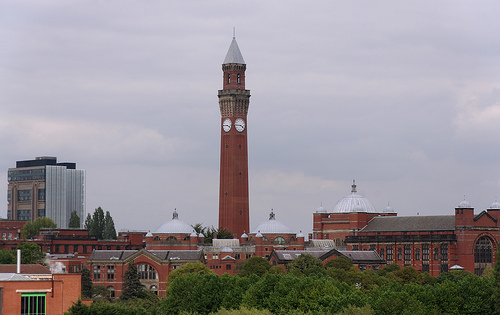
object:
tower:
[216, 26, 251, 239]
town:
[0, 25, 500, 314]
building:
[6, 155, 87, 231]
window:
[18, 189, 32, 201]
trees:
[414, 271, 436, 287]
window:
[107, 265, 114, 280]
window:
[93, 265, 101, 280]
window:
[149, 285, 158, 298]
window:
[106, 285, 116, 300]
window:
[21, 292, 46, 315]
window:
[38, 189, 46, 203]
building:
[1, 271, 84, 314]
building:
[88, 244, 205, 299]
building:
[265, 248, 390, 297]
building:
[344, 195, 499, 281]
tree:
[118, 256, 145, 301]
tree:
[373, 289, 429, 314]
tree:
[480, 274, 500, 314]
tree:
[61, 294, 93, 314]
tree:
[241, 277, 280, 315]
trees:
[323, 257, 352, 271]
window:
[474, 235, 498, 278]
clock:
[234, 118, 246, 133]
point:
[268, 208, 275, 221]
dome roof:
[331, 192, 377, 213]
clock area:
[221, 117, 248, 136]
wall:
[231, 117, 249, 244]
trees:
[240, 255, 274, 278]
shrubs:
[210, 305, 275, 314]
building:
[12, 19, 499, 294]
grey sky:
[1, 0, 499, 240]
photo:
[4, 6, 479, 308]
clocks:
[222, 118, 233, 133]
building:
[312, 178, 397, 241]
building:
[239, 208, 305, 259]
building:
[145, 208, 205, 251]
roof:
[152, 219, 199, 233]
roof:
[250, 219, 294, 233]